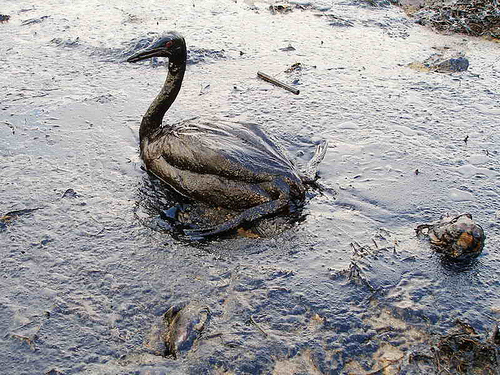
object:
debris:
[0, 2, 498, 374]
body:
[148, 115, 304, 209]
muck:
[1, 4, 497, 373]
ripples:
[27, 30, 225, 73]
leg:
[209, 194, 292, 244]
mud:
[0, 0, 498, 373]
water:
[0, 1, 499, 374]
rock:
[152, 295, 219, 353]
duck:
[122, 29, 311, 241]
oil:
[0, 1, 497, 374]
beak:
[125, 44, 160, 65]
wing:
[162, 132, 272, 183]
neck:
[142, 54, 192, 126]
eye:
[165, 39, 175, 50]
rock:
[416, 208, 486, 273]